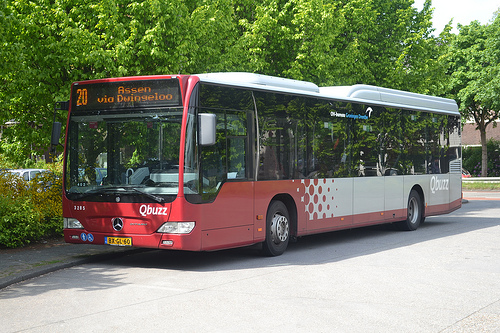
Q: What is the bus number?
A: 20.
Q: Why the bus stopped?
A: To take a rest.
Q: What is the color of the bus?
A: Red and white.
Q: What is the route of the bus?
A: Via dwingeloo.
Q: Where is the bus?
A: Parked at the sidewalk.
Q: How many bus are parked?
A: One.